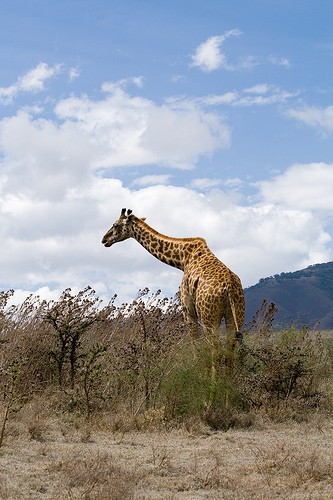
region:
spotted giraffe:
[92, 202, 252, 357]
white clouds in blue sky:
[13, 124, 73, 168]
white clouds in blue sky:
[16, 144, 62, 194]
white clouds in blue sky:
[15, 228, 75, 272]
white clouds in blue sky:
[98, 151, 150, 191]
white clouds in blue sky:
[165, 120, 233, 185]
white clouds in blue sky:
[238, 115, 299, 158]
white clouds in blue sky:
[241, 208, 285, 254]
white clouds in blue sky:
[231, 134, 277, 191]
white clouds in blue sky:
[242, 148, 303, 207]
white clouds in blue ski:
[3, 10, 62, 69]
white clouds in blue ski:
[99, 37, 171, 95]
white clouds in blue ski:
[198, 80, 266, 141]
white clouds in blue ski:
[232, 213, 287, 255]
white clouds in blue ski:
[136, 142, 202, 203]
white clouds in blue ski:
[196, 36, 247, 86]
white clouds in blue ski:
[44, 83, 134, 154]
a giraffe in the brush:
[102, 203, 254, 435]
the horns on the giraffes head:
[116, 204, 140, 221]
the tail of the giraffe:
[224, 287, 245, 342]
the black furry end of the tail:
[234, 328, 243, 343]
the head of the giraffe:
[97, 207, 142, 247]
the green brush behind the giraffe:
[146, 336, 229, 433]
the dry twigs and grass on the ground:
[10, 418, 331, 498]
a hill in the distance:
[244, 254, 330, 337]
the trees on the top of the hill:
[256, 257, 331, 293]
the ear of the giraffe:
[125, 213, 134, 228]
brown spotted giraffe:
[99, 212, 249, 362]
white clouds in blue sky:
[11, 16, 69, 83]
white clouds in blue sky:
[5, 86, 72, 175]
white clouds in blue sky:
[16, 173, 73, 228]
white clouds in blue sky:
[35, 67, 137, 127]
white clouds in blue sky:
[102, 78, 185, 130]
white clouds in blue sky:
[152, 34, 233, 103]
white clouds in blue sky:
[243, 87, 300, 145]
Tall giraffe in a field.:
[101, 206, 260, 426]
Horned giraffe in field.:
[101, 204, 247, 418]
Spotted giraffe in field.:
[101, 206, 247, 424]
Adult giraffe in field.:
[102, 208, 245, 418]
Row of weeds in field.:
[11, 291, 185, 416]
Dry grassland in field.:
[60, 433, 314, 495]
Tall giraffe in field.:
[102, 205, 246, 420]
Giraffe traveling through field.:
[101, 206, 245, 419]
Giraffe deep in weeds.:
[102, 206, 248, 421]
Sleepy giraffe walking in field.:
[100, 206, 245, 421]